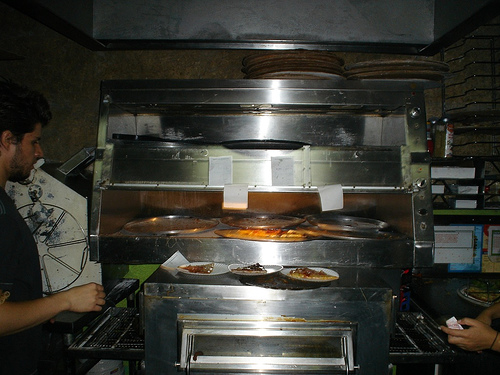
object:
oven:
[87, 80, 434, 268]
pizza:
[214, 228, 321, 241]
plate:
[177, 262, 230, 276]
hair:
[0, 86, 51, 142]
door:
[176, 314, 354, 374]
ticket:
[363, 116, 383, 146]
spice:
[164, 127, 186, 140]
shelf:
[103, 115, 410, 149]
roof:
[101, 76, 425, 109]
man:
[0, 87, 105, 374]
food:
[183, 263, 214, 274]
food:
[232, 263, 267, 273]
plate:
[228, 264, 283, 276]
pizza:
[289, 267, 338, 280]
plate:
[280, 267, 339, 282]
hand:
[62, 282, 106, 312]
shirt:
[0, 188, 44, 373]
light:
[256, 83, 287, 195]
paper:
[222, 183, 248, 210]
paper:
[5, 159, 103, 298]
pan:
[256, 71, 345, 80]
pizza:
[223, 217, 302, 228]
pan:
[221, 213, 307, 229]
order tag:
[271, 156, 295, 186]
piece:
[125, 217, 219, 235]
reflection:
[245, 78, 289, 374]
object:
[343, 58, 449, 70]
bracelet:
[490, 331, 500, 350]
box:
[447, 224, 483, 273]